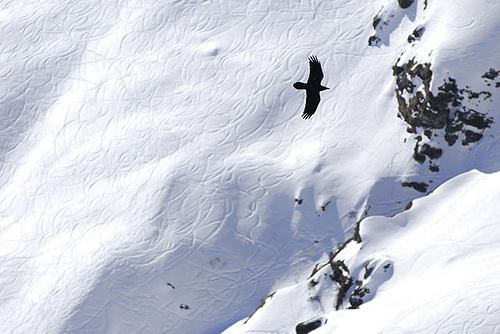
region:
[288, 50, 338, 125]
bird in flight over snow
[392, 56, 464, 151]
rock patches in snow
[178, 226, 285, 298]
shadow on white snow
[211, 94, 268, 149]
curved lines in snow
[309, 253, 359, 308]
exposed rock on hill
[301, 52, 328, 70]
feathers on wing tip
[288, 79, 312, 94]
tail on flying bird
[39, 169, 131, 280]
sun shine on snow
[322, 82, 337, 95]
beak on bird in flight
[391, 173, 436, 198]
exposed rock in crevice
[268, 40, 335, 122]
a bird flying on hair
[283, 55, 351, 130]
the bird is black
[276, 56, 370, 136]
the bird has wings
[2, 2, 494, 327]
there is snow on the ground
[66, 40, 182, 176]
the snow is white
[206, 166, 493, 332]
the snow is white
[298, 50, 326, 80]
the wing of a bird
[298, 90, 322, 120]
the wing of a bird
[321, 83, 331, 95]
the beak of a bird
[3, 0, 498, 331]
there is a bird in the photo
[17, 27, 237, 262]
the ground is covered in snow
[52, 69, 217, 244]
the snow has a swirl pattern in it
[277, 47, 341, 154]
a black bird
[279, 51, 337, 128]
the bird is flying over the mountain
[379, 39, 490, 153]
portions of rock poking out of the snow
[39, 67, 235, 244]
the snow is white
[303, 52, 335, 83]
the wing of the bird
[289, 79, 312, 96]
the tail of the bird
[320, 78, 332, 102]
the head of the bird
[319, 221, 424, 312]
rocks peeking through the snow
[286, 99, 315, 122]
edge of a wing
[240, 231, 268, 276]
part of some lines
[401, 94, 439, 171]
edge of a hill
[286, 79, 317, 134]
edge of a wing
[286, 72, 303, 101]
part of a tail wing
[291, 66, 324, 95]
back of a bird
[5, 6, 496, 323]
a scene of winter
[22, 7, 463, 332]
a scene with lots of snow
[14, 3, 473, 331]
a scene outside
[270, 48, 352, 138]
a bird flying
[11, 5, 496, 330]
snow covering mountains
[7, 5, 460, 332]
a white landscape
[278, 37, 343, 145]
a black bird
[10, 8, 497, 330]
scene during the day time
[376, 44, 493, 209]
dry spot of moutain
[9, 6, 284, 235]
tracks in the snow